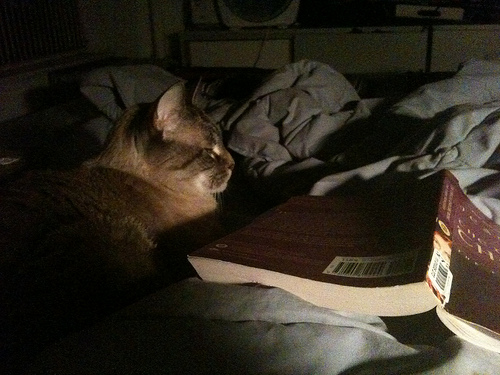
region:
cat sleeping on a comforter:
[0, 69, 242, 296]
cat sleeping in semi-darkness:
[4, 88, 249, 304]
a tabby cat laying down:
[13, 93, 248, 305]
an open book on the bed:
[189, 164, 498, 357]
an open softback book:
[185, 156, 498, 357]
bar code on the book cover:
[324, 248, 411, 282]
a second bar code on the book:
[422, 251, 461, 302]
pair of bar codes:
[309, 251, 464, 303]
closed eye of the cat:
[197, 131, 226, 164]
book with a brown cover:
[187, 167, 498, 351]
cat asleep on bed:
[0, 75, 238, 309]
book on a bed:
[178, 157, 497, 355]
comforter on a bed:
[265, 62, 487, 149]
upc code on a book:
[322, 240, 430, 288]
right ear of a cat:
[145, 78, 190, 133]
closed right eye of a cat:
[199, 138, 217, 158]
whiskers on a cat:
[206, 190, 226, 205]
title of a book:
[452, 211, 499, 276]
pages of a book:
[194, 260, 436, 330]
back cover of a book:
[181, 173, 440, 297]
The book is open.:
[236, 230, 496, 312]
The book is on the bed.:
[266, 158, 496, 374]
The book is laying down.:
[218, 146, 496, 324]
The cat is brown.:
[104, 87, 199, 274]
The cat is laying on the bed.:
[50, 83, 233, 308]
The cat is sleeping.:
[8, 76, 261, 331]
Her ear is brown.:
[152, 79, 193, 136]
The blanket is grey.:
[240, 76, 477, 137]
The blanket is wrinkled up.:
[93, 58, 497, 186]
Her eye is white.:
[197, 137, 228, 158]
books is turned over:
[181, 162, 498, 356]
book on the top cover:
[186, 168, 499, 370]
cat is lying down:
[3, 84, 239, 319]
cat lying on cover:
[0, 75, 245, 327]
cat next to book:
[3, 63, 245, 327]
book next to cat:
[178, 150, 494, 369]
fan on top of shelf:
[206, 0, 306, 42]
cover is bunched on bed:
[46, 51, 498, 183]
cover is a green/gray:
[8, 52, 499, 374]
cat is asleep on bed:
[4, 76, 266, 338]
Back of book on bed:
[188, 161, 449, 324]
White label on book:
[303, 242, 429, 284]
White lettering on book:
[291, 214, 356, 238]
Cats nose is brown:
[226, 159, 239, 170]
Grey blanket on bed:
[272, 78, 333, 129]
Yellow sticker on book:
[433, 216, 454, 237]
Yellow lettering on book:
[454, 224, 496, 255]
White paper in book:
[200, 264, 230, 279]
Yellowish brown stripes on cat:
[56, 166, 156, 234]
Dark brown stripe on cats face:
[170, 149, 207, 174]